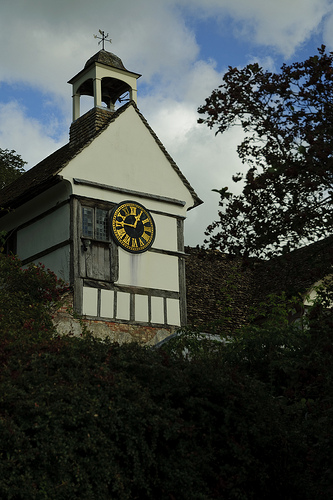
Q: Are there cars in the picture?
A: No, there are no cars.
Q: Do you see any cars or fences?
A: No, there are no cars or fences.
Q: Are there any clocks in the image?
A: Yes, there is a clock.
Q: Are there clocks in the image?
A: Yes, there is a clock.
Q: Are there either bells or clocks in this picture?
A: Yes, there is a clock.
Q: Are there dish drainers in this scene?
A: No, there are no dish drainers.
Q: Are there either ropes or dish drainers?
A: No, there are no dish drainers or ropes.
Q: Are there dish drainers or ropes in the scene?
A: No, there are no dish drainers or ropes.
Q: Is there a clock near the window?
A: Yes, there is a clock near the window.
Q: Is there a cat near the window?
A: No, there is a clock near the window.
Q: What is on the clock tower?
A: The clock is on the clock tower.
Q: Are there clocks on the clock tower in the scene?
A: Yes, there is a clock on the clock tower.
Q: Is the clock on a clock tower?
A: Yes, the clock is on a clock tower.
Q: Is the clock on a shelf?
A: No, the clock is on a clock tower.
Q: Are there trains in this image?
A: No, there are no trains.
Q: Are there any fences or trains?
A: No, there are no trains or fences.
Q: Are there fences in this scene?
A: No, there are no fences.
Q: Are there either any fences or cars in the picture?
A: No, there are no fences or cars.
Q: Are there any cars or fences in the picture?
A: No, there are no fences or cars.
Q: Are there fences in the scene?
A: No, there are no fences.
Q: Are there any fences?
A: No, there are no fences.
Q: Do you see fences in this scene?
A: No, there are no fences.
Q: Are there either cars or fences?
A: No, there are no fences or cars.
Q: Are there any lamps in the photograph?
A: No, there are no lamps.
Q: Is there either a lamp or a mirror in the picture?
A: No, there are no lamps or mirrors.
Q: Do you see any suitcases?
A: No, there are no suitcases.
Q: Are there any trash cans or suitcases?
A: No, there are no suitcases or trash cans.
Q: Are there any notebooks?
A: No, there are no notebooks.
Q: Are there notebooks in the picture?
A: No, there are no notebooks.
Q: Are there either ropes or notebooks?
A: No, there are no notebooks or ropes.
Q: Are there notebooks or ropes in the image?
A: No, there are no notebooks or ropes.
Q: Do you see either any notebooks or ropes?
A: No, there are no notebooks or ropes.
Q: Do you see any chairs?
A: No, there are no chairs.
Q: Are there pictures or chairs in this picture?
A: No, there are no chairs or pictures.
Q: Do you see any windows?
A: Yes, there is a window.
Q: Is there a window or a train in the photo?
A: Yes, there is a window.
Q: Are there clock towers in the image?
A: Yes, there is a clock tower.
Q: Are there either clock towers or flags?
A: Yes, there is a clock tower.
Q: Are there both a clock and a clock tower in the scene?
A: Yes, there are both a clock tower and a clock.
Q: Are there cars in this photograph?
A: No, there are no cars.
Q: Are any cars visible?
A: No, there are no cars.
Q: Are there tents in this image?
A: No, there are no tents.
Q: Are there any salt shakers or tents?
A: No, there are no tents or salt shakers.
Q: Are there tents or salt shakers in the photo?
A: No, there are no tents or salt shakers.